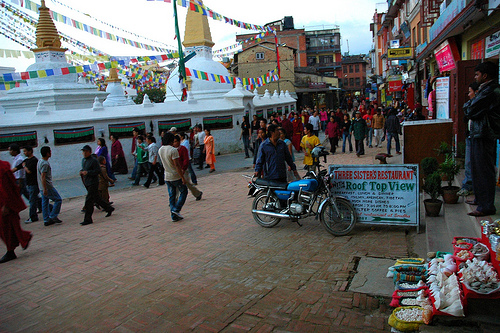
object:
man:
[252, 122, 298, 202]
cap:
[80, 144, 93, 153]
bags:
[393, 255, 427, 267]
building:
[229, 39, 301, 98]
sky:
[0, 0, 186, 66]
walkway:
[59, 229, 105, 253]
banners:
[182, 67, 193, 78]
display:
[422, 169, 447, 219]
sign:
[321, 161, 424, 235]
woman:
[202, 127, 219, 174]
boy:
[298, 122, 325, 176]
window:
[250, 49, 269, 62]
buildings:
[295, 65, 344, 110]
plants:
[435, 154, 465, 191]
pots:
[422, 196, 447, 219]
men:
[75, 144, 115, 226]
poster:
[328, 169, 416, 225]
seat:
[255, 176, 291, 187]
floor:
[115, 229, 283, 327]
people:
[107, 132, 130, 177]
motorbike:
[234, 170, 363, 239]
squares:
[0, 83, 111, 111]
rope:
[0, 51, 181, 75]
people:
[457, 61, 500, 218]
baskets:
[385, 303, 437, 333]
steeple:
[22, 0, 69, 72]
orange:
[202, 135, 218, 171]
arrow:
[366, 214, 415, 226]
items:
[440, 297, 468, 318]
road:
[0, 141, 398, 333]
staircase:
[422, 210, 483, 244]